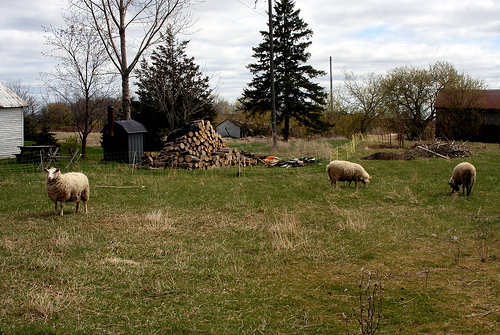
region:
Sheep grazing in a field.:
[6, 78, 492, 303]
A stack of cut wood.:
[157, 113, 260, 173]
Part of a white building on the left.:
[3, 80, 26, 162]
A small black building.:
[94, 104, 148, 163]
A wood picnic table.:
[17, 137, 66, 163]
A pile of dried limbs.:
[403, 130, 476, 155]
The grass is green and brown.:
[1, 136, 491, 329]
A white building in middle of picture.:
[212, 112, 244, 144]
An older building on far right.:
[428, 78, 498, 145]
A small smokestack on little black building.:
[96, 91, 144, 166]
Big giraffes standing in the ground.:
[325, 137, 422, 172]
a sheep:
[42, 163, 92, 214]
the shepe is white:
[324, 157, 368, 187]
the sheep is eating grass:
[443, 157, 476, 194]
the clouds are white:
[338, 27, 402, 67]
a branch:
[350, 283, 387, 330]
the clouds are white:
[335, 17, 394, 55]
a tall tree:
[241, 7, 325, 129]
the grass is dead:
[120, 199, 252, 275]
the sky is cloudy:
[341, 28, 416, 63]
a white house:
[1, 91, 23, 160]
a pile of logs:
[140, 107, 255, 182]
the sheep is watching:
[36, 155, 104, 223]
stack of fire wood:
[184, 127, 220, 164]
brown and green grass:
[183, 205, 288, 286]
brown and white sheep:
[315, 159, 362, 199]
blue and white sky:
[363, 17, 425, 68]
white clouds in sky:
[347, 10, 397, 65]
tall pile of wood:
[165, 103, 230, 183]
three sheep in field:
[42, 133, 495, 290]